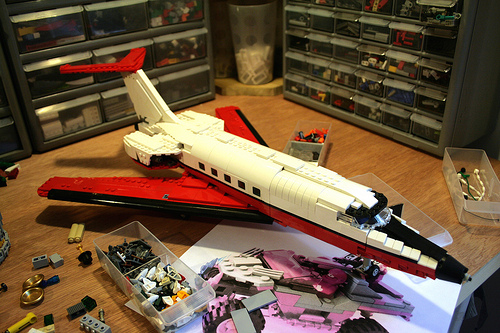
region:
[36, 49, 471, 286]
a Lego airplane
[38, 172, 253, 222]
red and black airplane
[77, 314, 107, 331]
a gray Lego piece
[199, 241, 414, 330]
pink vehicle on the paper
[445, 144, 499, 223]
a clear storage drawer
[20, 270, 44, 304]
two round brass pieces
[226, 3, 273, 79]
a cup with parts in it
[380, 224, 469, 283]
black nose of the plane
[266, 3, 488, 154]
gray storage box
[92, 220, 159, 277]
gray pieces in the drawer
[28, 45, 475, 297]
the plane is red and white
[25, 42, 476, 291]
plane made of legos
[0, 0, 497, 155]
legos in the shelves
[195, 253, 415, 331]
the legos are pink black and gray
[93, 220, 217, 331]
legos in the containers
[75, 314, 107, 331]
the lego is gray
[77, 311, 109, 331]
holes in the lego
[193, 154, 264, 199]
plane windows are black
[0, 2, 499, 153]
the shelves are gray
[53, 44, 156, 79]
top of plane wing is red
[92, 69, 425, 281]
white model plane on table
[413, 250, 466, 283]
black nose on plane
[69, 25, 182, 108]
red and white tail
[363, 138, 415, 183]
plane on brown desk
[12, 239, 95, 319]
grey bricks on table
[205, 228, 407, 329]
white paper with model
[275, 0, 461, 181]
grey cabinet with many drawers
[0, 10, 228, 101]
large drawers in cabinet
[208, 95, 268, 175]
red and black wing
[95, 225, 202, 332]
clear drawer with plastic blocks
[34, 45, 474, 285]
Toy plane on the table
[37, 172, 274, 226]
Right wing of the toy plane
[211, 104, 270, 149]
left wing of the toy plane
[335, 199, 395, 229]
Cockpit area of the plane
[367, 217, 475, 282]
Nose section of the toy plane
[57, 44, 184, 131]
Tail section of the plane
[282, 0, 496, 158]
Grey tool bin near the toy plane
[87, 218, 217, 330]
Transparent container with lego toy inside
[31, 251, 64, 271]
grey lego toy on the table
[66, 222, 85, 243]
Yellow lego near the plane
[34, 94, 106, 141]
lego drawer mostly filled with white pieces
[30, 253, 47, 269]
two by one grey lego piece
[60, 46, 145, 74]
red tail of a lego plane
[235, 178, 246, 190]
second window of a lego plane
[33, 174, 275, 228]
red and black wing of a lego plane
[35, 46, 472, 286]
red white, and black lego plane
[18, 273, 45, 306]
two golden metal rings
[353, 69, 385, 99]
drawer filled with legos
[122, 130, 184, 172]
the engine of a lego plane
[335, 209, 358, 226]
clear lego piece use as a window